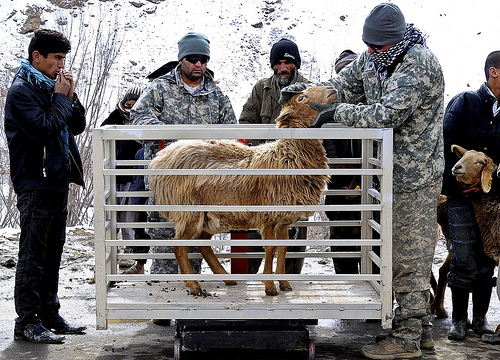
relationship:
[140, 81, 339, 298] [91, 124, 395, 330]
goat in pen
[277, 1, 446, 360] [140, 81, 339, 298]
man holding goat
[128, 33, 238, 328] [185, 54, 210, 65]
man wearing sunglasses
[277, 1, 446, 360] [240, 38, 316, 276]
man standing next to man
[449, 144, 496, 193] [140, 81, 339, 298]
goat to right of goat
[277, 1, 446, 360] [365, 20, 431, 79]
man wearing scarf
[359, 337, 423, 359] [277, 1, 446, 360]
boot of man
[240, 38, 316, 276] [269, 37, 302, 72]
man wearing hat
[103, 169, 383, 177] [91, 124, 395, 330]
metal strip of pen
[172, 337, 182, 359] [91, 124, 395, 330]
wheel under pen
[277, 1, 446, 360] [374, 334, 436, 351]
man wearing shoe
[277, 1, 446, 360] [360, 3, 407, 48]
man wearing cap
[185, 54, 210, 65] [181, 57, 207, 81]
sunglasses on face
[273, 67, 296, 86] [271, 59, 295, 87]
beard on face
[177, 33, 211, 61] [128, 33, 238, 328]
cap on man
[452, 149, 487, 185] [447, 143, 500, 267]
head of goat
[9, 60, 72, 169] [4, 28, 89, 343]
scarf on man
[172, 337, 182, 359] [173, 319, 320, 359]
wheel on cart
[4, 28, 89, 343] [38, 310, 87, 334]
man wearing shoe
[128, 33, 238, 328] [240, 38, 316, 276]
man next to man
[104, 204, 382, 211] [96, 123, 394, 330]
metal strip on cage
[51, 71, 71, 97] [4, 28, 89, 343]
hand of man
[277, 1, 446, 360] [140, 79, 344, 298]
man checking goat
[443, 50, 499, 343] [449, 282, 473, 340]
man wearing boot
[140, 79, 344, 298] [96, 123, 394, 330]
goat in cage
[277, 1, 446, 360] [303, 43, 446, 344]
man wearing camo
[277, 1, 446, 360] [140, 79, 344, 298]
man inspecting goat